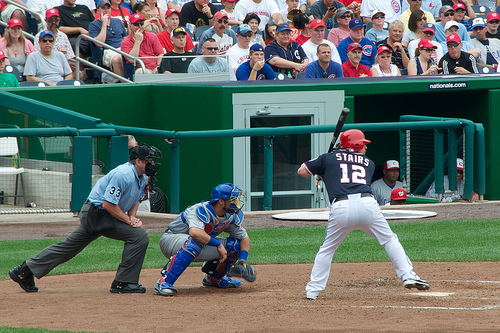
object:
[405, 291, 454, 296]
plate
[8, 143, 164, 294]
umpire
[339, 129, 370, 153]
helmet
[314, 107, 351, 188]
bat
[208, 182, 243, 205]
helmet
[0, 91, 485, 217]
railing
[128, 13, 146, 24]
hat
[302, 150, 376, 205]
jersey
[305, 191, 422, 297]
pants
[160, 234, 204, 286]
knee pad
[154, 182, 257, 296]
catcher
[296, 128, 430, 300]
batter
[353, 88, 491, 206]
dug out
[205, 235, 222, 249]
wristband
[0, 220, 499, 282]
grass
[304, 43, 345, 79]
spectator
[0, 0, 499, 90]
stand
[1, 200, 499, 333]
field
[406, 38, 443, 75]
woman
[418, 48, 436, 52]
sunglasses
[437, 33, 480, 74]
man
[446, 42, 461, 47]
sunglasses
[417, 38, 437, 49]
hat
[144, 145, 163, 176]
safety mask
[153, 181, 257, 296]
uniform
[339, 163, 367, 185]
number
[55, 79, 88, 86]
seat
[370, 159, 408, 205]
person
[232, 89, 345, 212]
door frame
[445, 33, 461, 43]
hat